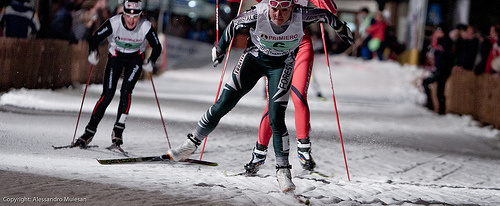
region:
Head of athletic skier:
[116, 0, 148, 32]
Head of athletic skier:
[260, 0, 302, 32]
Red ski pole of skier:
[317, 21, 361, 186]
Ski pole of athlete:
[151, 76, 175, 153]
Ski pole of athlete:
[69, 69, 87, 140]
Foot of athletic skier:
[167, 131, 199, 165]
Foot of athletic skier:
[240, 156, 268, 176]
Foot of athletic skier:
[272, 161, 298, 192]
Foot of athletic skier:
[293, 146, 323, 181]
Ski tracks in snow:
[371, 143, 446, 204]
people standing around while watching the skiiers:
[415, 20, 499, 117]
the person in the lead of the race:
[168, 2, 351, 182]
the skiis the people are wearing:
[49, 140, 341, 205]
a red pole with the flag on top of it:
[314, 1, 390, 186]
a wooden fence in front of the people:
[451, 60, 499, 125]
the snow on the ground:
[2, 65, 493, 205]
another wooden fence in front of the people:
[0, 35, 95, 93]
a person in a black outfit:
[83, 13, 158, 151]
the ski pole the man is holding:
[138, 65, 179, 154]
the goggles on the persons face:
[268, 0, 290, 9]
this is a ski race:
[9, 7, 499, 182]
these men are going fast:
[30, 18, 497, 184]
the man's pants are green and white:
[220, 52, 323, 178]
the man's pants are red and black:
[281, 72, 336, 164]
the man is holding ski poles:
[183, 4, 362, 157]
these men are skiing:
[65, 111, 490, 182]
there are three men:
[69, 15, 384, 190]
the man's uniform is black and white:
[58, 19, 173, 181]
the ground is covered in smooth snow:
[18, 168, 140, 204]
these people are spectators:
[376, 3, 498, 79]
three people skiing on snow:
[61, 0, 366, 199]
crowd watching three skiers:
[351, 8, 498, 124]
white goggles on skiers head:
[270, 3, 290, 9]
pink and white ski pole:
[315, 20, 360, 188]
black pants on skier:
[165, 48, 316, 198]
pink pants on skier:
[248, 40, 319, 173]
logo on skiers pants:
[277, 56, 294, 94]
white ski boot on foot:
[170, 136, 201, 165]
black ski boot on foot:
[74, 126, 98, 146]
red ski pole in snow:
[142, 57, 179, 153]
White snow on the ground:
[27, 143, 109, 186]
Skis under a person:
[61, 127, 170, 162]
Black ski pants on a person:
[85, 53, 150, 161]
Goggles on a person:
[113, 0, 149, 27]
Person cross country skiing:
[218, 1, 336, 203]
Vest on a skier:
[237, 8, 313, 65]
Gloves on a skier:
[203, 36, 230, 73]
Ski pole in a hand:
[206, 3, 231, 58]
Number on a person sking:
[261, 34, 310, 61]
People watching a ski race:
[370, 6, 499, 101]